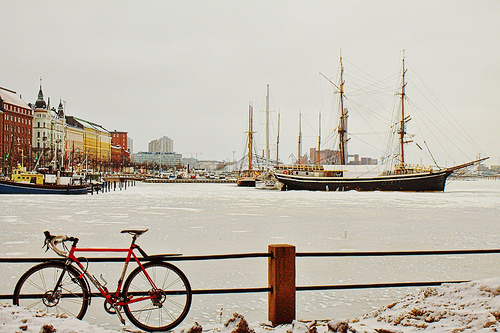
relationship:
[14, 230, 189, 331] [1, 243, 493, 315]
bike at fence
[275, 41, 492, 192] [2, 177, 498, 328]
ship on water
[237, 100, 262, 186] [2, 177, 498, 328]
ship on water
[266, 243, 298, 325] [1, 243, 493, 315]
post for fence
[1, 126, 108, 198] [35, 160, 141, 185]
ship black st dock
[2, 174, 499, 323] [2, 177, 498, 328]
snow covers water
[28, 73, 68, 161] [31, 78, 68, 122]
building with spires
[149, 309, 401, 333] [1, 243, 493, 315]
rocks next to fence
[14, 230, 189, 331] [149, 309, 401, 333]
bike by rocks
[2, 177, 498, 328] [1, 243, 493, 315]
water beyond fence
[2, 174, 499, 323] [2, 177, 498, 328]
snow over water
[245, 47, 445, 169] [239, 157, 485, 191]
masts over ships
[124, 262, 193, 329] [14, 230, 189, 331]
tire on a bike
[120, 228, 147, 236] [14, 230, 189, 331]
seat on bike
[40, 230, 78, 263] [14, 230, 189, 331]
handle bars on bike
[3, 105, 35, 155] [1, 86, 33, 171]
windows on a building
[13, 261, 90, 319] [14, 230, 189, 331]
wheel os a bike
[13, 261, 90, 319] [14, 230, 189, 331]
tire on a bike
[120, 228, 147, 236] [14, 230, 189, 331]
seat of bike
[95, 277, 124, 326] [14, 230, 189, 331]
pedals of bike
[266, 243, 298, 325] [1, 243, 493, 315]
post of fence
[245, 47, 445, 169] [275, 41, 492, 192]
masts on ship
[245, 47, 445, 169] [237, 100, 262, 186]
masts of ship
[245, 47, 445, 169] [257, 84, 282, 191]
masts of a ship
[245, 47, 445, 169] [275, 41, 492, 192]
masts of a ship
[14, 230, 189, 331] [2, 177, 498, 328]
bike parked near water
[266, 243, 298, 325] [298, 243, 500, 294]
post supports cables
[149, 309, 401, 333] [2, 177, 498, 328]
rocks along water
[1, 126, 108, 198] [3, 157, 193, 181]
ship along pier